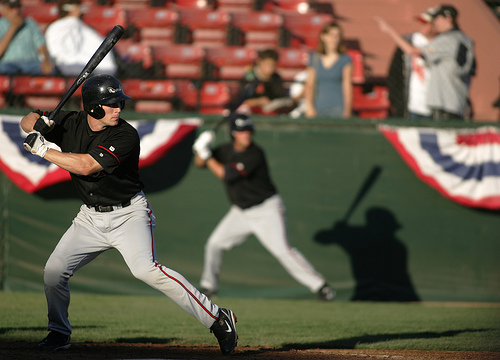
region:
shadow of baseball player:
[332, 165, 443, 319]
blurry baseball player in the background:
[204, 105, 340, 294]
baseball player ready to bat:
[27, 72, 261, 353]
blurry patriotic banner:
[376, 113, 498, 197]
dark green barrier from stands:
[296, 146, 379, 193]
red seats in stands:
[158, 14, 274, 77]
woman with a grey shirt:
[320, 24, 358, 133]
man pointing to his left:
[382, 0, 494, 140]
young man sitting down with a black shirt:
[224, 42, 295, 133]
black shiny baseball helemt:
[84, 70, 133, 123]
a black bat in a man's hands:
[24, 18, 125, 149]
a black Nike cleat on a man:
[212, 299, 242, 357]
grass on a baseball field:
[5, 290, 496, 342]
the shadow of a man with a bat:
[308, 161, 434, 301]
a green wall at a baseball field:
[0, 107, 498, 297]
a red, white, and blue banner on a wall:
[376, 121, 499, 206]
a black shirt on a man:
[207, 135, 277, 208]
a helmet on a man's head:
[77, 71, 131, 122]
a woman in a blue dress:
[303, 19, 357, 119]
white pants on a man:
[36, 201, 231, 334]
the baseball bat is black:
[17, 15, 152, 136]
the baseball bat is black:
[55, 31, 217, 186]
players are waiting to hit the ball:
[38, 29, 325, 320]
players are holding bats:
[18, 17, 309, 324]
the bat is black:
[45, 35, 89, 127]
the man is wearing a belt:
[49, 186, 158, 217]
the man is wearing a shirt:
[36, 104, 149, 216]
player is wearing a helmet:
[50, 65, 141, 132]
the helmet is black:
[52, 35, 145, 132]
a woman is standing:
[296, 20, 373, 142]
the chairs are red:
[144, 15, 244, 122]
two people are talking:
[367, 13, 494, 125]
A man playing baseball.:
[25, 21, 242, 357]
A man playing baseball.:
[189, 65, 352, 322]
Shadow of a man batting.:
[327, 155, 429, 325]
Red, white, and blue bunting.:
[360, 123, 498, 215]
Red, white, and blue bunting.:
[1, 112, 201, 196]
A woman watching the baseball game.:
[298, 17, 356, 133]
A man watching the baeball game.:
[0, 1, 48, 88]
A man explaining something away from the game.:
[408, 12, 480, 141]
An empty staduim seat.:
[145, 43, 215, 81]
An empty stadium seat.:
[241, 13, 283, 49]